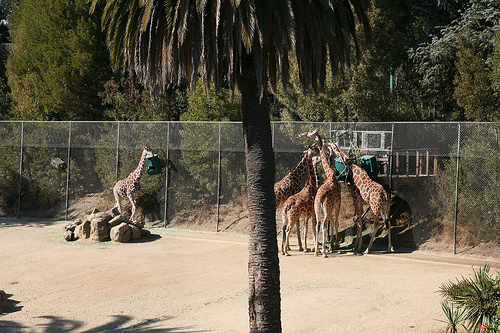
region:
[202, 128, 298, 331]
a very long tree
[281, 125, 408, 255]
a group of giraffe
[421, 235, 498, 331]
a small green tree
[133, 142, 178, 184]
face of the giraffe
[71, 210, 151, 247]
hard rocks beside giraffe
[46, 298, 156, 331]
shadow of the trees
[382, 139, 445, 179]
a small wooden bridge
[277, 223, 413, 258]
legs of the giraffe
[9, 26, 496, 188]
a beautiful view of trees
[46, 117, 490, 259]
a very thick fence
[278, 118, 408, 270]
a whole mess of giraffe's hanging around one feeding bin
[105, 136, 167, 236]
a lone, & lonely, seemingly ostracized giraffe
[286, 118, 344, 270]
the largest giraffe taking a gander at the lonely one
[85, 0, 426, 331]
a palm tree symbolically splitting the haves from the have-alones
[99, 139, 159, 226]
ostracized giraffe is fairly small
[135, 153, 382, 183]
food bins are dark teal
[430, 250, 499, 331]
plant, lower right, is leafy+frizzy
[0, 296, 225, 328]
palm tree shadow, lower left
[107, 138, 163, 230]
lonely giraffe is pretending nothing's wrong, staring at giraffes & into food bin, hoping for a simple invitation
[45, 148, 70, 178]
a videocamera behind the fence pointed at, of all animals, ostracized giraffe. what an odd photo, this one!!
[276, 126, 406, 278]
A tower of giraffes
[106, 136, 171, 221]
A lone giraffe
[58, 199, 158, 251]
A group of rocks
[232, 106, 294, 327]
A brown tree trunk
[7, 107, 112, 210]
A fence with trees behind it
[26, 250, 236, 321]
Tan sandy dirt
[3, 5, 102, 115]
Green tree top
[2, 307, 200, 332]
A shadow on the ground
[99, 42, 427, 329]
Giraffes eating from containers on the fence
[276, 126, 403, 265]
A back view of several giraffes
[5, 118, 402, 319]
group of giraffes in image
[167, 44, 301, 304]
large palm tree in front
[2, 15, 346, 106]
palm fronds hanging down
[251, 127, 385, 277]
huddle of giraffes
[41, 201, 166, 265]
large group of rocks on ground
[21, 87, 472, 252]
large metal fence by giraffes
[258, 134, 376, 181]
giraffe necks reaching out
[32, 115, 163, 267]
giraffe alone away from others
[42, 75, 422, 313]
group of animals in an enclosed area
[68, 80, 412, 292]
wild animals held by fence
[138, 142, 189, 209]
Giraffe eating out of a bucket.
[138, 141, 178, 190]
Bucket on fence is green.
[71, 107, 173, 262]
Tall fence next to giraffe.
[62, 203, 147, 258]
Large pile of rocks next to giraffe.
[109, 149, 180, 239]
Giraffe is brown and white.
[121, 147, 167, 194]
Giraffe has long neck.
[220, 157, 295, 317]
Trunk of tree is grayish brown.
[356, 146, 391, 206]
Green bucket attached to fence.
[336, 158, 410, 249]
Giraffe is brown and white.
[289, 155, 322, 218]
Giraffe is brown and white.